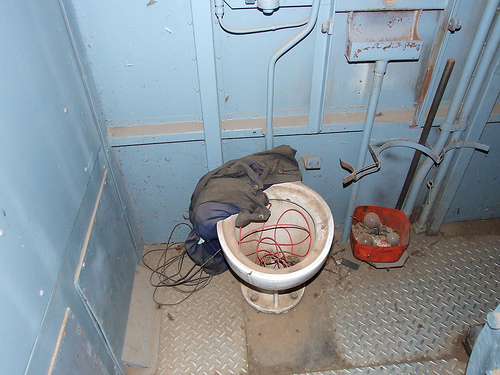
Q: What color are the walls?
A: Blue.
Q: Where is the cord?
A: Toilet.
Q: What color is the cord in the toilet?
A: Red.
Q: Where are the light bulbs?
A: Orange container.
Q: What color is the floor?
A: Silver.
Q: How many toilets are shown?
A: One.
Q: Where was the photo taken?
A: In a bathroom.